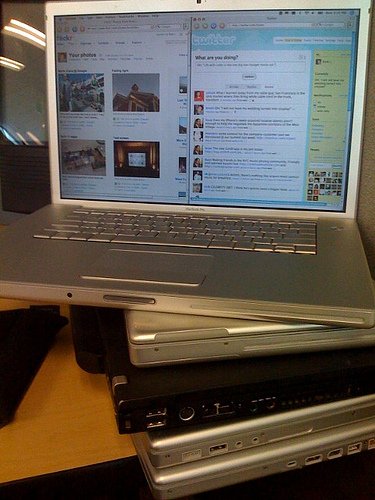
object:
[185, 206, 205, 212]
brand name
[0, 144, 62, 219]
wall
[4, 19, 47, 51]
ceiling light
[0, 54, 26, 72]
ceiling light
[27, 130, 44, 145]
ceiling light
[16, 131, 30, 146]
ceiling light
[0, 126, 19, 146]
ceiling light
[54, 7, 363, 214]
website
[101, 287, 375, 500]
pile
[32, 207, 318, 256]
keyboard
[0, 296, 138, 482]
desk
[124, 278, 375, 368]
laptop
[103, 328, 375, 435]
laptop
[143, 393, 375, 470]
laptop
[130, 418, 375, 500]
laptop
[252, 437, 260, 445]
headphone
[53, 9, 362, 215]
window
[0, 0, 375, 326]
computer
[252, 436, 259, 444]
holes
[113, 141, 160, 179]
photos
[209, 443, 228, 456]
plug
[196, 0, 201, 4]
camera lens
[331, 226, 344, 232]
button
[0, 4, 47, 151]
ceiling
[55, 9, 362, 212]
screen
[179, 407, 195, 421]
hole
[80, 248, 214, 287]
touch pad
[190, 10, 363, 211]
twittter page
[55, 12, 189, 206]
flikr page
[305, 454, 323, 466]
slot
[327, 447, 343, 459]
slot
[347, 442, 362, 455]
slot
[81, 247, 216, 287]
mouse pad